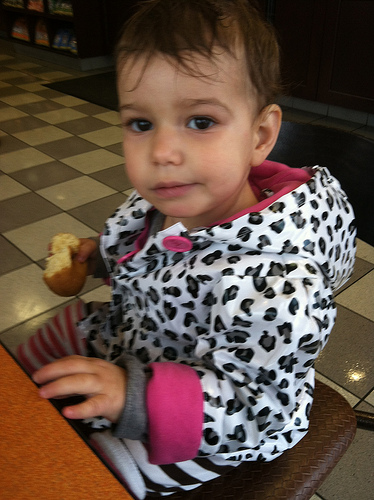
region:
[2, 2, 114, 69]
snack rack in the background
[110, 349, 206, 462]
rolled up coat sleeves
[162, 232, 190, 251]
pink button on jacket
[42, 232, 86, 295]
half eaten doughnut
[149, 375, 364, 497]
sitting on chair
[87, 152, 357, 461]
white black and pink print coat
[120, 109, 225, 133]
girl has brown eyes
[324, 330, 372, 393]
light bouncing off tiles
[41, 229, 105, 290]
holding a snack in right hand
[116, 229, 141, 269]
second button on coat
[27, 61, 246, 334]
baby is holding a donut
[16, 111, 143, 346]
baby is holding a donut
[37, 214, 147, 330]
baby is holding a donut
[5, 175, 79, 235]
the floor is tiled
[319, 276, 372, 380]
the floor is tiled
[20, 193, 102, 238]
the floor is tiled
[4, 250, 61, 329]
the floor is tiled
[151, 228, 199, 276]
the button is pink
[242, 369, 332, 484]
the seat is brown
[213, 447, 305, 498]
the seat is brown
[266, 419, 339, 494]
the seat is brown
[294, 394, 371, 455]
the seat is brown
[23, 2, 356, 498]
Toddler eating a donut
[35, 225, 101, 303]
Donut in a hand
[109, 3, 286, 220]
Toddler has brown hair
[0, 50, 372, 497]
Tiles on the floor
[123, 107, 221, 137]
A pair of brown eyes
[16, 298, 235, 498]
Stripes on the pants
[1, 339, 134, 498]
A brown wooden table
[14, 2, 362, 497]
Small child is sitting down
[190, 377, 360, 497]
A brown leather chair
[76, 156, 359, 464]
Black, white and pink jacket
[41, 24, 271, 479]
the young girl is eating a doughnut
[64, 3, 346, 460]
a young girl sitting at at table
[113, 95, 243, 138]
the girl has brown eyes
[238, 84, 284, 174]
the young girls ear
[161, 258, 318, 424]
the girls jacket has leapord spots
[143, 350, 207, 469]
her jacket has pink cuffs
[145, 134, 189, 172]
the young girls nose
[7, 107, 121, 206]
the ground is covered in with and gray tile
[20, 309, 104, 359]
the girls pants have stripes on them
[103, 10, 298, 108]
the young girl has brown hair